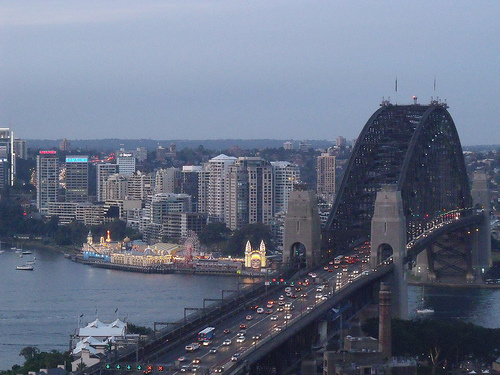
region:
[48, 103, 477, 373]
bridge spanning the river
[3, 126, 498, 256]
buildings alone the river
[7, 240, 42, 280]
boats in the river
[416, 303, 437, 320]
boat traveling under rbidge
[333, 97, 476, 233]
black arch of the bridge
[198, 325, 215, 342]
bus traveling down the bridge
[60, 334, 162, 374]
traffic signals on the bridge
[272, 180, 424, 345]
stone pillars supporting the middle of the bridge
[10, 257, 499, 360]
river bridge is over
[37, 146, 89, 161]
lighted signs atop two buildings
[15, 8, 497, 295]
this is a twilight setting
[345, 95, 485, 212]
this is a suspension bridge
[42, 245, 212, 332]
this is a river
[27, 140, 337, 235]
this is a big city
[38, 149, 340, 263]
this is the city's skyline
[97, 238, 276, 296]
the waterfront is lit up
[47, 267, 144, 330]
the water is dark blue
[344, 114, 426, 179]
the bridge is made of steel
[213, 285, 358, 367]
there is traffic on the bridge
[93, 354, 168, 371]
these are traffic lights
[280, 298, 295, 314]
this is a van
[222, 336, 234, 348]
this is a car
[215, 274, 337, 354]
these are the vehicles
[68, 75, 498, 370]
this is a bridge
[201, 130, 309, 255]
this is a skyscraper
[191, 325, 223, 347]
this is a bus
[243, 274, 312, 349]
these are the cars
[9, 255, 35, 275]
this is a boat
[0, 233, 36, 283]
these are the boats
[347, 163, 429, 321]
this is a pillar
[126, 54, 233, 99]
Hazy blue overcast sky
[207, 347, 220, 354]
Small car on bridge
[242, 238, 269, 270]
Ornate building near water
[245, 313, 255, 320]
Small vehicle on bridge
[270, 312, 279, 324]
Small vehicle on bridge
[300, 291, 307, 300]
Small vehicle on bridge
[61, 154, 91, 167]
Blue roof of building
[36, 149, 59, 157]
Red roof on building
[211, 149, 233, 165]
Blue roof on building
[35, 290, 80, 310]
Calm blue river water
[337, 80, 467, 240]
bridge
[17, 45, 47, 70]
white clouds in blue sky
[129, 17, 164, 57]
white clouds in blue sky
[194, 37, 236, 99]
white clouds in blue sky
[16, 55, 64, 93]
white clouds in blue sky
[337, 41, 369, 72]
white clouds in blue sky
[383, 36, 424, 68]
white clouds in blue sky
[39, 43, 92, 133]
white clouds in blue sky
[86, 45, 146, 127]
white clouds in blue sky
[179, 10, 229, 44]
white clouds in blue sky